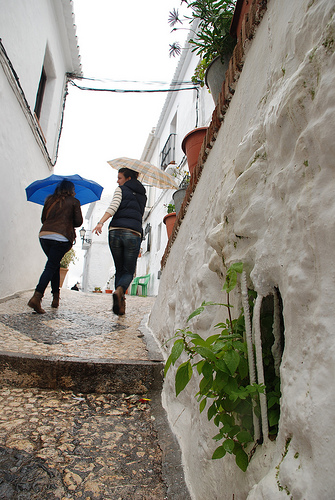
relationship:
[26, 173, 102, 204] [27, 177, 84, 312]
umbrella on woman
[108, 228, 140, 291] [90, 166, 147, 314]
pants on woman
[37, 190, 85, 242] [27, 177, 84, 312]
jacket on woman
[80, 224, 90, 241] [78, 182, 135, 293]
light on building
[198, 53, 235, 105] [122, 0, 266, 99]
pots with plants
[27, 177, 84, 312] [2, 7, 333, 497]
woman in rain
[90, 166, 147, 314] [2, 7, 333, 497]
woman in rain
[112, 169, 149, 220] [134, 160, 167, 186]
woman holding umbrella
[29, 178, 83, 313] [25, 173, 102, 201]
women holding umbrellas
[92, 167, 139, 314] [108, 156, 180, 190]
women holding umbrellas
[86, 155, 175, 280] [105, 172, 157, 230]
woman wearing jacket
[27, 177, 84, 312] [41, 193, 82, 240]
woman wearing jacket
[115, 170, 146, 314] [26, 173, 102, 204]
girl with umbrella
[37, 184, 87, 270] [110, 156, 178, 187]
girl with umbrella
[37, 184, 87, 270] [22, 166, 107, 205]
girl with umbrella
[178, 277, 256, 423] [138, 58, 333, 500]
plants on wall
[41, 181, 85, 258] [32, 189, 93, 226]
girl wearing jacket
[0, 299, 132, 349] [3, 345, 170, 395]
diamond pattern on step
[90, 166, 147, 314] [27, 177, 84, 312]
woman walking with woman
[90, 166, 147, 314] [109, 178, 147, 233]
woman wearing vest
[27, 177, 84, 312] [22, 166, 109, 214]
woman with umbrella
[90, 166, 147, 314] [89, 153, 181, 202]
woman with umbrella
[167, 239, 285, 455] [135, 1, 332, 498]
plant growing from wall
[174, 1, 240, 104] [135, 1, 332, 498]
plant growing from wall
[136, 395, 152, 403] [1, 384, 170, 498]
leaf on ground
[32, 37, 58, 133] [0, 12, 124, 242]
window on building